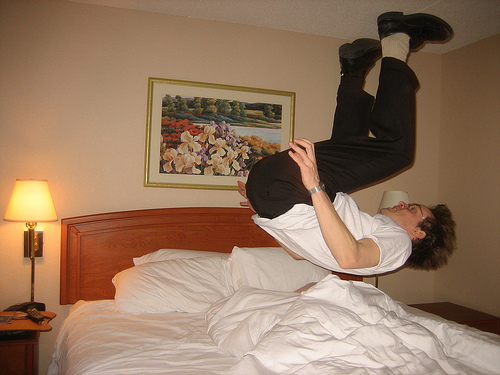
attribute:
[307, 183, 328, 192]
watch — silver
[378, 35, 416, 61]
sock — tan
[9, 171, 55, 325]
light — on, orange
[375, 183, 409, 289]
light — off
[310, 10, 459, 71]
shoes — black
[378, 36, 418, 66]
socks — tan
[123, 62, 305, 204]
frame — gold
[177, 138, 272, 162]
flowers — colorful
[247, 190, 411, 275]
tee shirt — cotton, white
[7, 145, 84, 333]
lamp — illuminated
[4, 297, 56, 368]
nightstand — cluttered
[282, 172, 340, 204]
watch — silver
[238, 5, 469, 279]
man — doing a flip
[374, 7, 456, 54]
shoe — black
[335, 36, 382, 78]
shoe — black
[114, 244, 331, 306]
pillows — white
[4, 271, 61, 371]
stand — light brown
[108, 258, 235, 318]
pillow — white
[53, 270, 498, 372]
comforter — down, white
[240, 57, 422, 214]
pants — black, long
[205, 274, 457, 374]
comforter — white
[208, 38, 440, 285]
man — doing a flip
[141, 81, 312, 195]
picture — floral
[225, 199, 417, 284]
shirt — white